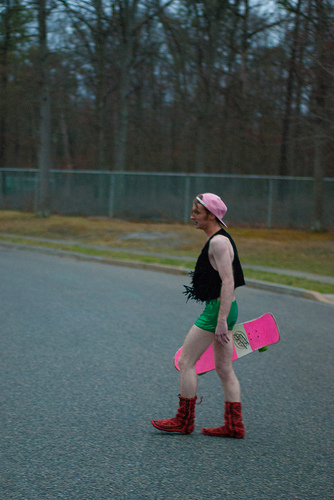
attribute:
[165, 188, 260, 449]
man — walking, pale, girly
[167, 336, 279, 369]
skateboard — pink, white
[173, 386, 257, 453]
shoes — red, boots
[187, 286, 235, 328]
shorts — green, short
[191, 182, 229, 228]
ball cap — backwards, pink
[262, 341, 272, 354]
wheels — green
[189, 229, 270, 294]
vest — black, ripped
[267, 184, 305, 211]
fence — chain link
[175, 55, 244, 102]
trees — tall, blurred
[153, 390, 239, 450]
boots — red, heeless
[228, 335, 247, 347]
design — black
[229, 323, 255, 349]
line — white